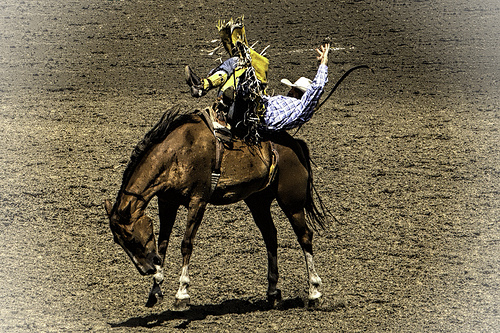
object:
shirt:
[262, 62, 330, 132]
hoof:
[264, 285, 282, 311]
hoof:
[302, 289, 326, 309]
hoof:
[167, 288, 192, 314]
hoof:
[143, 285, 165, 310]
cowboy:
[180, 42, 342, 136]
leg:
[172, 193, 210, 290]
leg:
[146, 191, 180, 290]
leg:
[273, 194, 324, 294]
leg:
[242, 195, 281, 293]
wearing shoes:
[180, 62, 230, 99]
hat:
[278, 76, 313, 92]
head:
[97, 194, 164, 276]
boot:
[180, 65, 228, 99]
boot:
[213, 84, 235, 115]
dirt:
[0, 0, 498, 332]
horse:
[99, 104, 348, 313]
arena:
[0, 0, 499, 332]